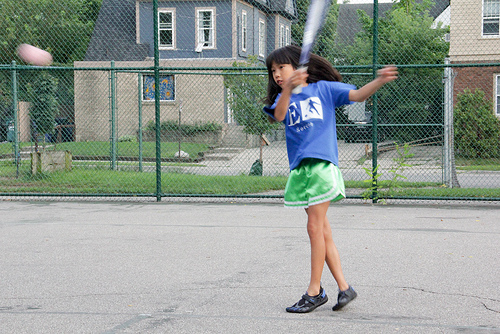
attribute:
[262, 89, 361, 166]
shirt — blue and white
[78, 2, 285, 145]
house — blue top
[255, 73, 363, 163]
shirt — blue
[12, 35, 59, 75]
ball — faded, light red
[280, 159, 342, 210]
shorts — green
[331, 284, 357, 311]
shoe — black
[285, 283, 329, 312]
shoe — black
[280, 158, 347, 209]
shorts — green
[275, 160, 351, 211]
shorts — green and white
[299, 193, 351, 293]
legs — tan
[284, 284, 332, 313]
shoe — dark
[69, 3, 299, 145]
house — blue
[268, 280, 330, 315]
shoe — black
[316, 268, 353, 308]
shoe — black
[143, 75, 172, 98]
curtain — blue and orange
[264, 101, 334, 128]
emblem — white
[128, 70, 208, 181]
poles — green 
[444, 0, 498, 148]
house — tan top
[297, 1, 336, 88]
bat — blurry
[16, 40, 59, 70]
ball — airborne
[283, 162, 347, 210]
shorts — green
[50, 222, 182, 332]
concrete — gray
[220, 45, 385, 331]
girl — bare legs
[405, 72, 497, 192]
fence — chain, link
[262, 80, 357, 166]
shirt — short-sleeve, blue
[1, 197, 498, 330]
concrete — grey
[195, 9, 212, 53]
curtain — white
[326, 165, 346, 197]
stripe — white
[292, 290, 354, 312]
shoes — black and blue, toe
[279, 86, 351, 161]
shirt — blue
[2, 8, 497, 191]
fence — green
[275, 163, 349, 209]
trim — white